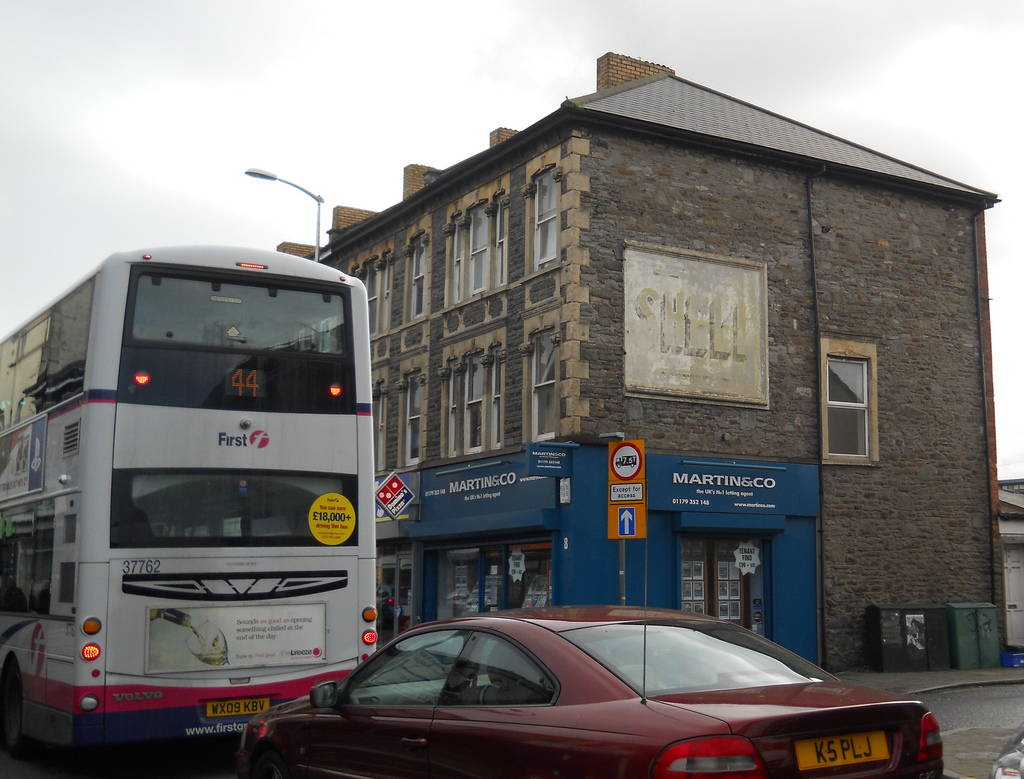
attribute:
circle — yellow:
[272, 474, 398, 563]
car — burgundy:
[330, 586, 905, 772]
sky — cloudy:
[43, 18, 393, 191]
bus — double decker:
[5, 225, 431, 768]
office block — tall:
[219, 52, 995, 722]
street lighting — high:
[216, 149, 338, 249]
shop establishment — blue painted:
[415, 454, 852, 696]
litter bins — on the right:
[852, 599, 1013, 673]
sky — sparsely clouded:
[13, 3, 1018, 477]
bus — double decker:
[15, 225, 387, 723]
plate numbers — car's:
[783, 733, 900, 777]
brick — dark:
[845, 465, 967, 571]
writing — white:
[651, 467, 790, 520]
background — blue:
[635, 450, 813, 528]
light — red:
[76, 629, 118, 666]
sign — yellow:
[288, 482, 360, 556]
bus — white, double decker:
[439, 705, 489, 768]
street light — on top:
[231, 154, 342, 269]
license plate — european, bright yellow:
[783, 728, 917, 778]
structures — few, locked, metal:
[864, 577, 1003, 688]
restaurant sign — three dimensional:
[359, 465, 414, 528]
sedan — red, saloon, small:
[236, 607, 950, 778]